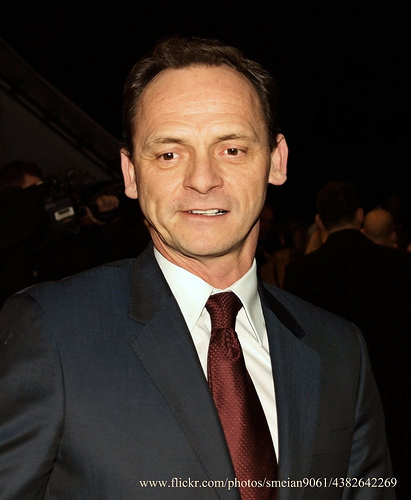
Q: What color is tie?
A: Red.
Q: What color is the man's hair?
A: Brown.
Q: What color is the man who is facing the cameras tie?
A: Mahogany.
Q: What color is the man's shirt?
A: White.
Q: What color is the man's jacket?
A: Blue.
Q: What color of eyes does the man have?
A: Brown.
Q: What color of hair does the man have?
A: Brown.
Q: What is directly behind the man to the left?
A: A cameraman.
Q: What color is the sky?
A: Black.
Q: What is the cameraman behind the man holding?
A: A video camera.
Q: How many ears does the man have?
A: 2.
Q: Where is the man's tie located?
A: Around his neck.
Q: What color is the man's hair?
A: Brown.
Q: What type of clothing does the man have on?
A: A suit and tie.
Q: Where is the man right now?
A: A formal event.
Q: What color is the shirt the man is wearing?
A: White.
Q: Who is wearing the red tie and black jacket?
A: The man facing the camera.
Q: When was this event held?
A: At night.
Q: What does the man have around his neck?
A: A tie.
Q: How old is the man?
A: Middle-aged.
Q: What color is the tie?
A: Maroon.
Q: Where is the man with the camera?
A: On the left.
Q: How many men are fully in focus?
A: 1.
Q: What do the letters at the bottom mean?
A: The web address for the photo on Flickr.